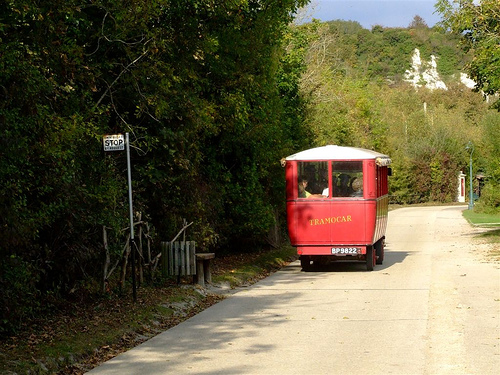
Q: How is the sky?
A: Clear.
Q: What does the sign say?
A: Stop.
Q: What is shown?
A: A bus.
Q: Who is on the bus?
A: Passengers.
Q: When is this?
A: During the day.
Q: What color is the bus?
A: Red.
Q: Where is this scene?
A: At the park.